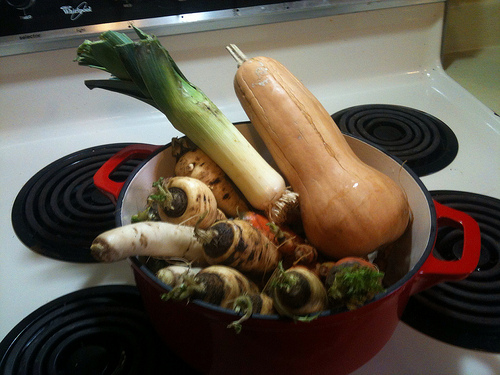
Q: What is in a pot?
A: Vegetables.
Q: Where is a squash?
A: In a pot.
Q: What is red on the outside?
A: The pot.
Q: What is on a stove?
A: A red pot.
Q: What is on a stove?
A: Black burner.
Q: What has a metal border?
A: Stove.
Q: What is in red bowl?
A: Veggies.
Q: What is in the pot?
A: Vegetables.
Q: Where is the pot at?
A: On stove.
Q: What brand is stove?
A: Whirlpool.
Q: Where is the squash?
A: In red pot.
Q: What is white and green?
A: Leek.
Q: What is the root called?
A: Turnips.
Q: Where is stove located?
A: Kitchen.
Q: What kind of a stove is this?
A: A white stove.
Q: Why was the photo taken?
A: For a magazine.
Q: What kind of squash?
A: Butternut squash.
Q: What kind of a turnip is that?
A: A yellow turnip.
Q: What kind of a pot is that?
A: A red pot.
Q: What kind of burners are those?
A: Black burners.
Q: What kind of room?
A: A kitchen.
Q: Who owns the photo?
A: Jake Zeke.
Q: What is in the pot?
A: Vegetables.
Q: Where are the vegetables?
A: In the pot.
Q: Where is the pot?
A: A stove.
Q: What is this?
A: Veggies.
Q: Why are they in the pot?
A: To get clean.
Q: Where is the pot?
A: On the stove.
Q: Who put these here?
A: Person.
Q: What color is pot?
A: Red.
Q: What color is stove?
A: White.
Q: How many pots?
A: 1.